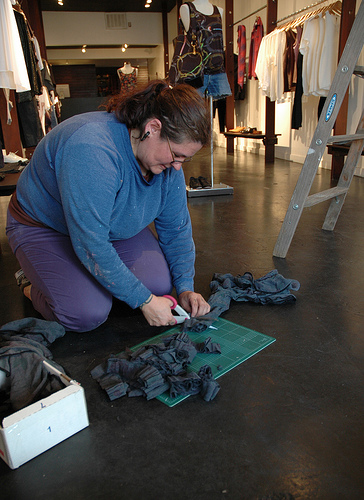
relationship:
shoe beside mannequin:
[188, 175, 201, 190] [180, 0, 235, 199]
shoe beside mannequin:
[197, 173, 210, 189] [180, 0, 235, 199]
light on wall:
[78, 40, 96, 63] [41, 9, 164, 87]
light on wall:
[120, 40, 127, 52] [41, 9, 164, 87]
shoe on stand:
[197, 173, 210, 189] [182, 98, 238, 200]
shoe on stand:
[188, 175, 201, 190] [182, 98, 238, 200]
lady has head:
[3, 74, 218, 334] [111, 66, 212, 196]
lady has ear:
[3, 74, 218, 334] [145, 119, 163, 140]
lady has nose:
[3, 74, 218, 334] [168, 155, 185, 171]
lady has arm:
[3, 74, 218, 334] [50, 144, 154, 306]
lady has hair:
[3, 74, 218, 334] [107, 62, 204, 147]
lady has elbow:
[3, 74, 218, 334] [66, 226, 110, 260]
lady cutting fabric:
[3, 74, 218, 334] [88, 264, 301, 407]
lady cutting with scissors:
[3, 74, 218, 334] [161, 291, 218, 330]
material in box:
[0, 315, 66, 418] [0, 359, 91, 470]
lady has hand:
[3, 74, 218, 334] [138, 293, 180, 330]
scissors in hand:
[158, 290, 220, 334] [138, 293, 180, 330]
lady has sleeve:
[3, 74, 218, 334] [44, 150, 210, 309]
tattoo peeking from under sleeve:
[136, 291, 158, 305] [44, 150, 210, 309]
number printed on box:
[43, 423, 52, 432] [0, 359, 91, 470]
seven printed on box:
[39, 401, 45, 407] [3, 365, 88, 469]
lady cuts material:
[3, 74, 218, 334] [91, 259, 302, 412]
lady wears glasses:
[3, 74, 218, 334] [158, 127, 192, 166]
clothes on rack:
[255, 11, 341, 103] [266, 1, 345, 185]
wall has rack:
[169, 99, 205, 128] [266, 1, 345, 185]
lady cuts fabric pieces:
[3, 74, 218, 334] [87, 336, 230, 396]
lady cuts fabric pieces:
[3, 74, 218, 334] [210, 271, 300, 310]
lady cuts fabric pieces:
[3, 74, 218, 334] [0, 318, 62, 389]